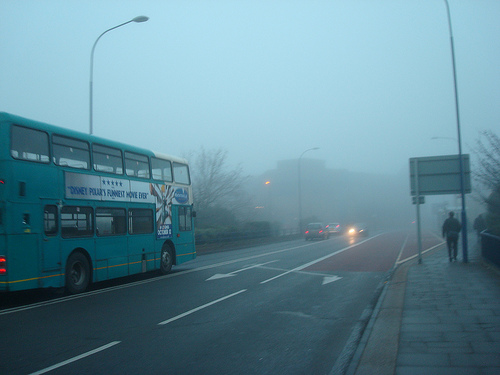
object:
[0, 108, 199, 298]
blue bus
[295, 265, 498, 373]
ground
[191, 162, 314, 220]
building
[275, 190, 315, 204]
corner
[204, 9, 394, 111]
sky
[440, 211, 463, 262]
man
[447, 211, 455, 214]
goggles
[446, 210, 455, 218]
head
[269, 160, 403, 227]
building